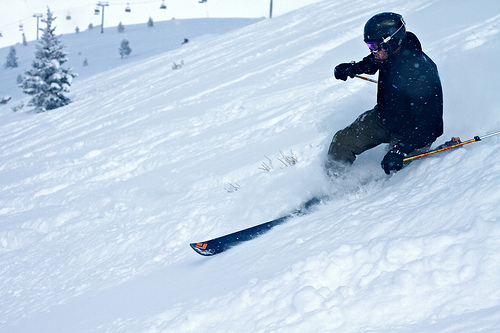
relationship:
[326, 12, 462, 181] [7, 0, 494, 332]
man skiing slope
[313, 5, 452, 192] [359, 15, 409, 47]
man wearing helmet